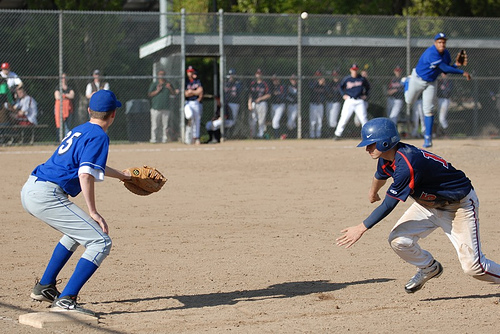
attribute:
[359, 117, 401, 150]
helmet — blue